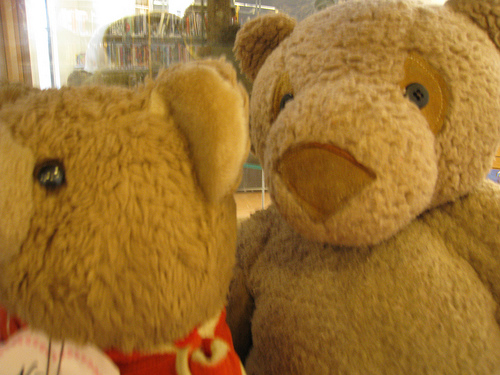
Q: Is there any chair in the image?
A: No, there are no chairs.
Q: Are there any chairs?
A: No, there are no chairs.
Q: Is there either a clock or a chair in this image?
A: No, there are no chairs or clocks.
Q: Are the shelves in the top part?
A: Yes, the shelves are in the top of the image.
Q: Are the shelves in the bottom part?
A: No, the shelves are in the top of the image.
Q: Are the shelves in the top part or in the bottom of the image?
A: The shelves are in the top of the image.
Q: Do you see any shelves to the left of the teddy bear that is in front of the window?
A: Yes, there are shelves to the left of the teddy bear.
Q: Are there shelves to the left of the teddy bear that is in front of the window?
A: Yes, there are shelves to the left of the teddy bear.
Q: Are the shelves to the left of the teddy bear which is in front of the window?
A: Yes, the shelves are to the left of the teddy bear.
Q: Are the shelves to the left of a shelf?
A: No, the shelves are to the left of the teddy bear.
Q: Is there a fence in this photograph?
A: No, there are no fences.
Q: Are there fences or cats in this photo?
A: No, there are no fences or cats.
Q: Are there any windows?
A: Yes, there is a window.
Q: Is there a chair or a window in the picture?
A: Yes, there is a window.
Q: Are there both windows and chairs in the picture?
A: No, there is a window but no chairs.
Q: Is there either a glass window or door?
A: Yes, there is a glass window.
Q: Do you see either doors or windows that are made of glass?
A: Yes, the window is made of glass.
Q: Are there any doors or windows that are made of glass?
A: Yes, the window is made of glass.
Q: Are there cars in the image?
A: No, there are no cars.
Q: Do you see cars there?
A: No, there are no cars.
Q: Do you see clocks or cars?
A: No, there are no cars or clocks.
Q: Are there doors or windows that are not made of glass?
A: No, there is a window but it is made of glass.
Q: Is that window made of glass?
A: Yes, the window is made of glass.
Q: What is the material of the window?
A: The window is made of glass.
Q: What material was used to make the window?
A: The window is made of glass.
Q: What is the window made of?
A: The window is made of glass.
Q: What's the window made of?
A: The window is made of glass.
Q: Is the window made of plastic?
A: No, the window is made of glass.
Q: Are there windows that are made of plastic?
A: No, there is a window but it is made of glass.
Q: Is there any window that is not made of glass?
A: No, there is a window but it is made of glass.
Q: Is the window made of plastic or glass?
A: The window is made of glass.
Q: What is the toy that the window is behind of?
A: The toy is a teddy bear.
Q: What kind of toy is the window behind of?
A: The window is behind the teddy bear.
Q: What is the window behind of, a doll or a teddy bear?
A: The window is behind a teddy bear.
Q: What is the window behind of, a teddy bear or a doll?
A: The window is behind a teddy bear.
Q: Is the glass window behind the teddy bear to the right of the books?
A: Yes, the window is behind the teddy bear.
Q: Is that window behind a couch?
A: No, the window is behind the teddy bear.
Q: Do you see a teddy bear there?
A: Yes, there is a teddy bear.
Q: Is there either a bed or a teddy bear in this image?
A: Yes, there is a teddy bear.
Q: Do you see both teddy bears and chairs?
A: No, there is a teddy bear but no chairs.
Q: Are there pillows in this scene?
A: No, there are no pillows.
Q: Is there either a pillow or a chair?
A: No, there are no pillows or chairs.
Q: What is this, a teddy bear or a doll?
A: This is a teddy bear.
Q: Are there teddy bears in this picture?
A: Yes, there is a teddy bear.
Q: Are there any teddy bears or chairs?
A: Yes, there is a teddy bear.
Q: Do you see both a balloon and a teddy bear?
A: No, there is a teddy bear but no balloons.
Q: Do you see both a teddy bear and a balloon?
A: No, there is a teddy bear but no balloons.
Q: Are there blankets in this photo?
A: No, there are no blankets.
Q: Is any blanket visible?
A: No, there are no blankets.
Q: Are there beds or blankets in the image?
A: No, there are no blankets or beds.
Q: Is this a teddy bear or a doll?
A: This is a teddy bear.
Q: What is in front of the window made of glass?
A: The teddy bear is in front of the window.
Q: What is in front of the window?
A: The teddy bear is in front of the window.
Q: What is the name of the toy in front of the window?
A: The toy is a teddy bear.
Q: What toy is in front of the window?
A: The toy is a teddy bear.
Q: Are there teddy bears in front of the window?
A: Yes, there is a teddy bear in front of the window.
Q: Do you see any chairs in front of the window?
A: No, there is a teddy bear in front of the window.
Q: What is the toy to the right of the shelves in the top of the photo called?
A: The toy is a teddy bear.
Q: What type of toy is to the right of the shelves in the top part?
A: The toy is a teddy bear.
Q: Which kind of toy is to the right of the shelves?
A: The toy is a teddy bear.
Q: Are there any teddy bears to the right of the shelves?
A: Yes, there is a teddy bear to the right of the shelves.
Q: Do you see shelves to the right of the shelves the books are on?
A: No, there is a teddy bear to the right of the shelves.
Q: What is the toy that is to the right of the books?
A: The toy is a teddy bear.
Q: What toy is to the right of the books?
A: The toy is a teddy bear.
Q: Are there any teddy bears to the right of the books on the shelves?
A: Yes, there is a teddy bear to the right of the books.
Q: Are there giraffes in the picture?
A: No, there are no giraffes.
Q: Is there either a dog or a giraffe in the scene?
A: No, there are no giraffes or dogs.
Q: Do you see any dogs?
A: No, there are no dogs.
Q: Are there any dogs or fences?
A: No, there are no dogs or fences.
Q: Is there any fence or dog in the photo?
A: No, there are no dogs or fences.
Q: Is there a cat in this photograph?
A: No, there are no cats.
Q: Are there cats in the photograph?
A: No, there are no cats.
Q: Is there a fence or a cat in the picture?
A: No, there are no cats or fences.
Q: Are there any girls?
A: No, there are no girls.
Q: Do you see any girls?
A: No, there are no girls.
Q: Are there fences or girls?
A: No, there are no girls or fences.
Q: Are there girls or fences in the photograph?
A: No, there are no girls or fences.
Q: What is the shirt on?
A: The shirt is on the teddy bear.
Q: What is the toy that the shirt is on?
A: The toy is a teddy bear.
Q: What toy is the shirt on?
A: The shirt is on the teddy bear.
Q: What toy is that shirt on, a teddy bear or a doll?
A: The shirt is on a teddy bear.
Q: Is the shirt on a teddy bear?
A: Yes, the shirt is on a teddy bear.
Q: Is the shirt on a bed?
A: No, the shirt is on a teddy bear.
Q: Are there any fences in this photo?
A: No, there are no fences.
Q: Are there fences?
A: No, there are no fences.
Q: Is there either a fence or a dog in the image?
A: No, there are no fences or dogs.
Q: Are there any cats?
A: No, there are no cats.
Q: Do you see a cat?
A: No, there are no cats.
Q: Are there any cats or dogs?
A: No, there are no cats or dogs.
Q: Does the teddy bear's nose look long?
A: Yes, the nose is long.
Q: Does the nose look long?
A: Yes, the nose is long.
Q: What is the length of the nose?
A: The nose is long.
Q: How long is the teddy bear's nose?
A: The nose is long.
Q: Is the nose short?
A: No, the nose is long.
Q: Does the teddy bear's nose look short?
A: No, the nose is long.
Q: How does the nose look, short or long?
A: The nose is long.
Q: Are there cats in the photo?
A: No, there are no cats.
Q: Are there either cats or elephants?
A: No, there are no cats or elephants.